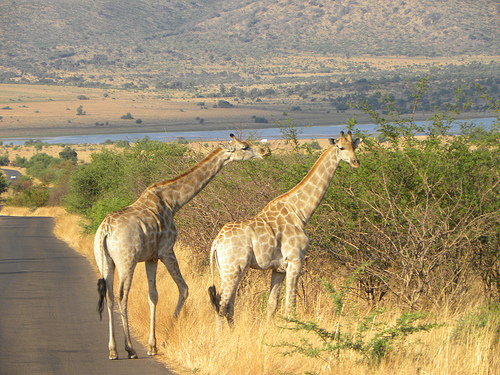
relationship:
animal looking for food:
[91, 133, 272, 360] [58, 66, 484, 323]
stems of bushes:
[328, 173, 483, 303] [2, 141, 493, 371]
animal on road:
[91, 133, 272, 360] [2, 211, 174, 373]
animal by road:
[207, 131, 359, 336] [2, 211, 174, 373]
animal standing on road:
[91, 133, 272, 360] [6, 206, 107, 366]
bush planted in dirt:
[74, 105, 85, 117] [2, 46, 487, 120]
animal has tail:
[91, 133, 272, 360] [91, 232, 118, 323]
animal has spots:
[207, 131, 359, 336] [274, 200, 302, 227]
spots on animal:
[255, 207, 300, 239] [199, 120, 378, 334]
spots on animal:
[140, 198, 166, 226] [210, 132, 396, 339]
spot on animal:
[182, 185, 191, 194] [91, 133, 272, 360]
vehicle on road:
[8, 169, 19, 183] [3, 171, 156, 373]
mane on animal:
[133, 146, 224, 180] [91, 133, 272, 360]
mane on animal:
[249, 134, 334, 210] [207, 131, 359, 336]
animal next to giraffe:
[207, 131, 359, 336] [88, 124, 276, 364]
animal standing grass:
[207, 131, 359, 336] [56, 237, 471, 373]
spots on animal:
[285, 193, 302, 210] [210, 115, 377, 316]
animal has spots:
[210, 115, 377, 316] [285, 193, 302, 210]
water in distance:
[0, 112, 486, 144] [1, 0, 466, 79]